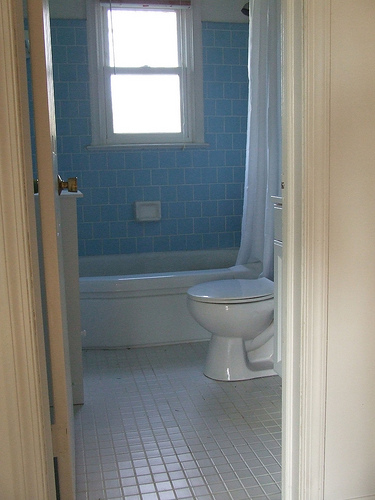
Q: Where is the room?
A: Bathroom.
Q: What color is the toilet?
A: White.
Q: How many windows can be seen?
A: 1.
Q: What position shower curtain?
A: Open.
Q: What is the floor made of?
A: Tile.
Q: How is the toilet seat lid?
A: Down.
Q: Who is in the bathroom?
A: No one.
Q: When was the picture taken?
A: Daytime.